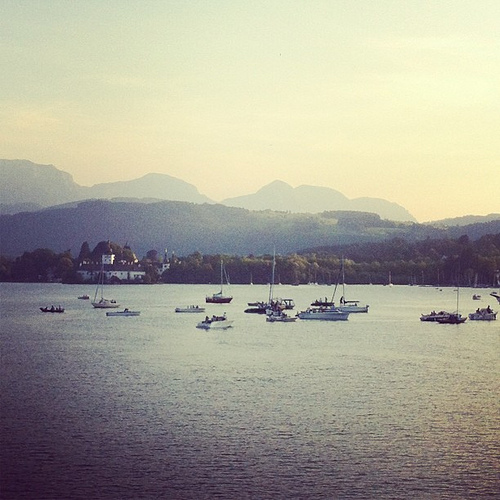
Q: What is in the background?
A: Mountains.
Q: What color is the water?
A: Blue.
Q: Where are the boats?
A: On the water.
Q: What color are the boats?
A: White.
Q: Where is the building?
A: In the distance.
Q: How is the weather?
A: Warm.